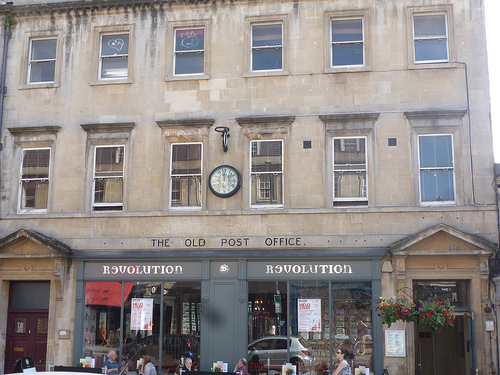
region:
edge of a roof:
[380, 217, 442, 250]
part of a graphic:
[319, 252, 356, 270]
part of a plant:
[409, 296, 436, 336]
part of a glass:
[115, 281, 153, 333]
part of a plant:
[382, 298, 430, 325]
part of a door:
[348, 155, 366, 205]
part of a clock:
[208, 153, 240, 200]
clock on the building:
[203, 161, 279, 204]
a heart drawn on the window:
[98, 36, 127, 63]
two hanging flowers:
[380, 285, 482, 341]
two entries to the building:
[3, 244, 499, 367]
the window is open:
[81, 169, 140, 234]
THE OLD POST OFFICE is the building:
[152, 236, 315, 248]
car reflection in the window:
[236, 310, 322, 372]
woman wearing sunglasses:
[322, 345, 347, 361]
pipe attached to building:
[0, 15, 6, 151]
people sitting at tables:
[98, 356, 253, 373]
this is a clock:
[205, 163, 246, 203]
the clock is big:
[206, 165, 244, 197]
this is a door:
[8, 274, 51, 371]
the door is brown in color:
[26, 316, 34, 326]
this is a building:
[4, 1, 496, 356]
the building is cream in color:
[203, 83, 322, 111]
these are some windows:
[252, 130, 466, 207]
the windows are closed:
[254, 128, 457, 205]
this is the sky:
[488, 10, 499, 35]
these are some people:
[33, 347, 370, 373]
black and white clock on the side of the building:
[205, 161, 242, 200]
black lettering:
[149, 236, 306, 248]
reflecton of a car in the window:
[249, 329, 314, 367]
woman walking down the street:
[322, 338, 356, 374]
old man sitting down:
[97, 346, 121, 373]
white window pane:
[248, 138, 288, 212]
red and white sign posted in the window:
[293, 296, 324, 334]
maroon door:
[3, 306, 48, 373]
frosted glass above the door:
[11, 278, 48, 320]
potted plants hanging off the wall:
[373, 276, 460, 336]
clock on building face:
[206, 162, 243, 199]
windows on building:
[18, 6, 460, 93]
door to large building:
[1, 301, 61, 374]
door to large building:
[404, 271, 487, 374]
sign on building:
[143, 235, 308, 251]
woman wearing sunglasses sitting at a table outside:
[322, 343, 358, 374]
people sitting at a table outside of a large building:
[96, 346, 163, 373]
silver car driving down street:
[239, 327, 320, 373]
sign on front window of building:
[292, 296, 326, 337]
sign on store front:
[96, 261, 187, 277]